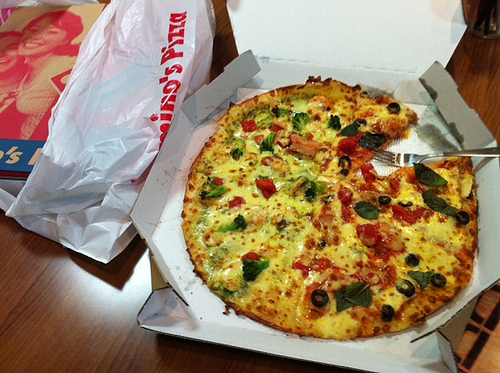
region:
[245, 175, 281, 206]
red toppings on pizza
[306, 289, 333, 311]
olive on the pizza pie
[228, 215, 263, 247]
gooey cheese on the pizza pie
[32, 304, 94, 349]
the brown dinner table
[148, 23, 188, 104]
red letters of the pizza shop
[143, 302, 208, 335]
a cardboard box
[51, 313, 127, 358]
a wooden table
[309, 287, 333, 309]
an olive on the pizza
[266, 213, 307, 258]
cheese on the pizza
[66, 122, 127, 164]
a plastic bag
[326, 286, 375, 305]
spinach on the pizza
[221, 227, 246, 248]
the cheese is yellow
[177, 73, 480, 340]
pizza in a cardboard box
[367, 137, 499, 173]
fork in a pizza box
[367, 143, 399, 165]
tines of a fork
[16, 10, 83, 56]
face of a woman on a box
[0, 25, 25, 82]
face of a man on a box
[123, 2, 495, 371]
a cardboard pizza box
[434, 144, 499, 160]
handle of a fork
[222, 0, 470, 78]
top of the pizza box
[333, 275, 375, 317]
two green leaves stacked on a pizza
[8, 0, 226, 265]
white pizza bag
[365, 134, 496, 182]
The fork in the pizza box.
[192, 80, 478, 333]
The pizza is round.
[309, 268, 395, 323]
The pizza has olives on it.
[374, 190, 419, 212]
The olives are black.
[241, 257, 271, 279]
The pizza has broccoli on it.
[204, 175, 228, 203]
The broccoli is green.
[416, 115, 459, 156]
The grease stain in the pizza box.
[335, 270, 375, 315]
The pizza has spinach on it.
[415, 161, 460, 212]
The spinach is green.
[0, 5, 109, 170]
The pizza box that is not open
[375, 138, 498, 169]
The fork is made of metal.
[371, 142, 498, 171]
The fork is silver in color.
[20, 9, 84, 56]
The woman is smiling.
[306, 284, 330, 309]
The olive is on the pizza.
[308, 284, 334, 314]
The olive is round.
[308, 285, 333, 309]
The olive is black in color.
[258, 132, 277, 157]
The broccoli is on the pizza.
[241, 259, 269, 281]
The broccoli is green in color.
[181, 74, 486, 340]
A personal pizza with toppings.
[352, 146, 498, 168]
A metal eating utensil.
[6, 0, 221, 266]
A bag next to a box.